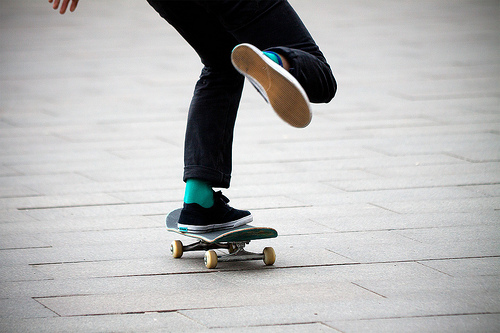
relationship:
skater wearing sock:
[45, 1, 337, 235] [182, 180, 218, 210]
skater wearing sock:
[45, 1, 337, 235] [262, 45, 282, 66]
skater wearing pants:
[45, 1, 337, 235] [147, 2, 336, 188]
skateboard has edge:
[167, 205, 278, 270] [164, 226, 278, 243]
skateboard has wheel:
[167, 205, 278, 270] [202, 249, 218, 269]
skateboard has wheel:
[167, 205, 278, 270] [264, 247, 277, 265]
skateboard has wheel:
[167, 205, 278, 270] [169, 240, 185, 260]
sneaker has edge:
[178, 189, 253, 233] [178, 214, 255, 232]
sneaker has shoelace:
[178, 189, 253, 233] [218, 188, 230, 204]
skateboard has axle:
[167, 205, 278, 270] [218, 243, 266, 262]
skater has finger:
[45, 1, 337, 235] [70, 0, 78, 14]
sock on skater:
[182, 180, 218, 210] [45, 1, 337, 235]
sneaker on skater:
[178, 189, 253, 233] [45, 1, 337, 235]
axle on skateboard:
[218, 243, 266, 262] [167, 205, 278, 270]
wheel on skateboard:
[202, 249, 218, 269] [167, 205, 278, 270]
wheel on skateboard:
[264, 247, 277, 265] [167, 205, 278, 270]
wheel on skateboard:
[169, 240, 185, 260] [167, 205, 278, 270]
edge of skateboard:
[164, 226, 278, 243] [167, 205, 278, 270]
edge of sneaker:
[178, 214, 255, 232] [178, 189, 253, 233]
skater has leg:
[45, 1, 337, 235] [205, 0, 337, 105]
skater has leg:
[45, 1, 337, 235] [161, 12, 244, 193]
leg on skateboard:
[161, 12, 244, 193] [167, 205, 278, 270]